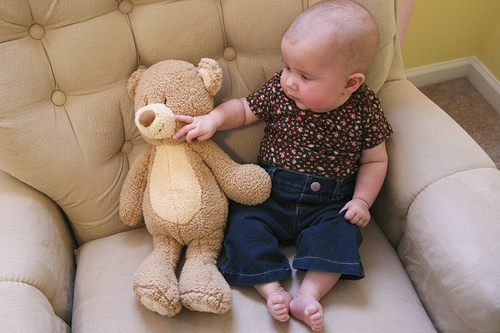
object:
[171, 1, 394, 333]
baby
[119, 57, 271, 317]
bear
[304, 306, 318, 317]
toes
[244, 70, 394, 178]
shirt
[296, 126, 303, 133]
flowers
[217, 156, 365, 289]
jeans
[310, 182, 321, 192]
button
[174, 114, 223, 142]
hand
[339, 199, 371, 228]
hand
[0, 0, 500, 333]
chair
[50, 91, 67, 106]
buttons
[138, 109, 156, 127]
nose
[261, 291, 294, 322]
feet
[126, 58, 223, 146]
head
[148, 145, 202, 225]
tummy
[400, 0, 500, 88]
wall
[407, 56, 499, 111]
baseboard